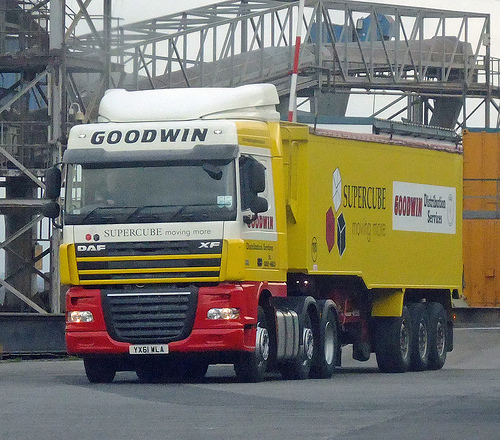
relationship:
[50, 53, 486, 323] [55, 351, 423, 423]
truck on street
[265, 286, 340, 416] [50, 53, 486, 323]
wheel on truck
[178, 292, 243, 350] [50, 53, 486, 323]
light on truck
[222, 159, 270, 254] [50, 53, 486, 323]
window on truck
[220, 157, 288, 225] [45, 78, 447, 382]
mirror on truck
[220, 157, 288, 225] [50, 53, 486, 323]
mirror on truck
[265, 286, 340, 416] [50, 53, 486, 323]
wheel of truck